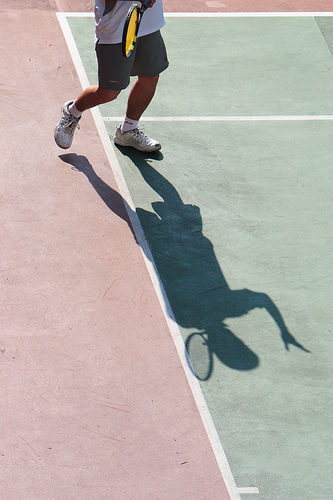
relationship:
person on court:
[52, 1, 171, 153] [2, 1, 332, 499]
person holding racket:
[52, 1, 171, 153] [121, 1, 153, 61]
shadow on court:
[57, 152, 311, 383] [2, 1, 332, 499]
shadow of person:
[57, 152, 311, 383] [52, 1, 171, 153]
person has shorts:
[52, 1, 171, 153] [95, 27, 170, 91]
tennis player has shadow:
[44, 2, 174, 159] [57, 152, 311, 383]